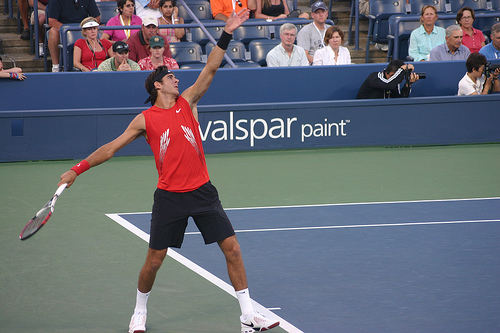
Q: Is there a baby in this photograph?
A: No, there are no babies.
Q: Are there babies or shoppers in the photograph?
A: No, there are no babies or shoppers.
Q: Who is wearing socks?
A: The man is wearing socks.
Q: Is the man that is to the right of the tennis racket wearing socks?
A: Yes, the man is wearing socks.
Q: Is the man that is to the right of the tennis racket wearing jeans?
A: No, the man is wearing socks.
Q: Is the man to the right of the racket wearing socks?
A: Yes, the man is wearing socks.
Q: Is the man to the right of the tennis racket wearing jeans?
A: No, the man is wearing socks.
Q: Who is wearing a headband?
A: The man is wearing a headband.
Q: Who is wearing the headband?
A: The man is wearing a headband.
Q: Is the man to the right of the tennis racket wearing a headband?
A: Yes, the man is wearing a headband.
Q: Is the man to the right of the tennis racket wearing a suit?
A: No, the man is wearing a headband.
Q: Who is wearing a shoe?
A: The man is wearing a shoe.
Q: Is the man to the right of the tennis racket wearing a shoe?
A: Yes, the man is wearing a shoe.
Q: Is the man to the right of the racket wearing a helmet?
A: No, the man is wearing a shoe.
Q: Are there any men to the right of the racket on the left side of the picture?
A: Yes, there is a man to the right of the tennis racket.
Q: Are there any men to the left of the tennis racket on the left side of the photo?
A: No, the man is to the right of the tennis racket.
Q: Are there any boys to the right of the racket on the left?
A: No, there is a man to the right of the tennis racket.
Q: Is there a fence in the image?
A: No, there are no fences.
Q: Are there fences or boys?
A: No, there are no fences or boys.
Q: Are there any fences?
A: No, there are no fences.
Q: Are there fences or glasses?
A: No, there are no fences or glasses.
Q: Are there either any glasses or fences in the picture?
A: No, there are no fences or glasses.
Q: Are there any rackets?
A: Yes, there is a racket.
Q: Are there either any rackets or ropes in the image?
A: Yes, there is a racket.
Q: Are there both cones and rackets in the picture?
A: No, there is a racket but no cones.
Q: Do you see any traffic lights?
A: No, there are no traffic lights.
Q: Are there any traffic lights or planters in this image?
A: No, there are no traffic lights or planters.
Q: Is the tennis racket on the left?
A: Yes, the tennis racket is on the left of the image.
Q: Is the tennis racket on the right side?
A: No, the tennis racket is on the left of the image.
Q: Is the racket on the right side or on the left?
A: The racket is on the left of the image.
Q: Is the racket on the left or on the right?
A: The racket is on the left of the image.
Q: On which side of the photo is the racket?
A: The racket is on the left of the image.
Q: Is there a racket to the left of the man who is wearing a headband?
A: Yes, there is a racket to the left of the man.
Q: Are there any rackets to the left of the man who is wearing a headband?
A: Yes, there is a racket to the left of the man.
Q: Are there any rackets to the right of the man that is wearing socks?
A: No, the racket is to the left of the man.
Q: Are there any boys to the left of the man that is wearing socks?
A: No, there is a racket to the left of the man.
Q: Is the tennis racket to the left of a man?
A: Yes, the tennis racket is to the left of a man.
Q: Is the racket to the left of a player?
A: No, the racket is to the left of a man.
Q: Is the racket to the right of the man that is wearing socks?
A: No, the racket is to the left of the man.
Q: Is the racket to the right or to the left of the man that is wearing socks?
A: The racket is to the left of the man.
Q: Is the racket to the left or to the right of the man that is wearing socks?
A: The racket is to the left of the man.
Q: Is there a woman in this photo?
A: Yes, there is a woman.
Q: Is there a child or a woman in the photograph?
A: Yes, there is a woman.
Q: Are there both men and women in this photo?
A: Yes, there are both a woman and a man.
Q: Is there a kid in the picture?
A: No, there are no children.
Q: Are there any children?
A: No, there are no children.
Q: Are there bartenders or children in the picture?
A: No, there are no children or bartenders.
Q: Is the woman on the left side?
A: Yes, the woman is on the left of the image.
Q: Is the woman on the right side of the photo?
A: No, the woman is on the left of the image.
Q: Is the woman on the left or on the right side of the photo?
A: The woman is on the left of the image.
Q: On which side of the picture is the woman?
A: The woman is on the left of the image.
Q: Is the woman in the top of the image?
A: Yes, the woman is in the top of the image.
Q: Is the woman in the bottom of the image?
A: No, the woman is in the top of the image.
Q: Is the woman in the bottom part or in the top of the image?
A: The woman is in the top of the image.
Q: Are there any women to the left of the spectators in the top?
A: Yes, there is a woman to the left of the spectators.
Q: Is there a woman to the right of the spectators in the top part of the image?
A: No, the woman is to the left of the spectators.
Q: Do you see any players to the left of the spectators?
A: No, there is a woman to the left of the spectators.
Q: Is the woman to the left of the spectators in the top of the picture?
A: Yes, the woman is to the left of the spectators.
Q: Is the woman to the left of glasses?
A: No, the woman is to the left of the spectators.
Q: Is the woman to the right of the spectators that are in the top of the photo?
A: No, the woman is to the left of the spectators.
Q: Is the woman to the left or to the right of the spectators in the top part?
A: The woman is to the left of the spectators.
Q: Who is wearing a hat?
A: The woman is wearing a hat.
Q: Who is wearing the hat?
A: The woman is wearing a hat.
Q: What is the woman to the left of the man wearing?
A: The woman is wearing a hat.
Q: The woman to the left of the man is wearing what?
A: The woman is wearing a hat.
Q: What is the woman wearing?
A: The woman is wearing a hat.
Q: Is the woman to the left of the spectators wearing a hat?
A: Yes, the woman is wearing a hat.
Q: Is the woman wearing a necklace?
A: No, the woman is wearing a hat.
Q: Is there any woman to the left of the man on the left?
A: Yes, there is a woman to the left of the man.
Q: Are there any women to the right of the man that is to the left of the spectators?
A: No, the woman is to the left of the man.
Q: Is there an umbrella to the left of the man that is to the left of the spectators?
A: No, there is a woman to the left of the man.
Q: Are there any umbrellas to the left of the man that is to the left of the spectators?
A: No, there is a woman to the left of the man.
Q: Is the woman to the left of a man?
A: Yes, the woman is to the left of a man.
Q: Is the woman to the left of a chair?
A: No, the woman is to the left of a man.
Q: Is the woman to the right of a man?
A: No, the woman is to the left of a man.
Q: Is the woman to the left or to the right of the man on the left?
A: The woman is to the left of the man.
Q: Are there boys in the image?
A: No, there are no boys.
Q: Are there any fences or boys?
A: No, there are no boys or fences.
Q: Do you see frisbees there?
A: No, there are no frisbees.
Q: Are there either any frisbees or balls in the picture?
A: No, there are no frisbees or balls.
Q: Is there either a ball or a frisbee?
A: No, there are no frisbees or balls.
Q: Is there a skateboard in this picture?
A: No, there are no skateboards.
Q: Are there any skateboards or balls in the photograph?
A: No, there are no skateboards or balls.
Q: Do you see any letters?
A: Yes, there are letters.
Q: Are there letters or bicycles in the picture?
A: Yes, there are letters.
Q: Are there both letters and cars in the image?
A: No, there are letters but no cars.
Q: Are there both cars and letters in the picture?
A: No, there are letters but no cars.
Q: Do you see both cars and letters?
A: No, there are letters but no cars.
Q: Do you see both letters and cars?
A: No, there are letters but no cars.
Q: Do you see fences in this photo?
A: No, there are no fences.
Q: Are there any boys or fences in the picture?
A: No, there are no fences or boys.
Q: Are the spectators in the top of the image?
A: Yes, the spectators are in the top of the image.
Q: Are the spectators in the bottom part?
A: No, the spectators are in the top of the image.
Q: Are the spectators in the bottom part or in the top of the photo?
A: The spectators are in the top of the image.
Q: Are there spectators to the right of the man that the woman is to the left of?
A: Yes, there are spectators to the right of the man.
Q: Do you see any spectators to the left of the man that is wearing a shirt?
A: No, the spectators are to the right of the man.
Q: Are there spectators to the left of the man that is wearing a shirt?
A: No, the spectators are to the right of the man.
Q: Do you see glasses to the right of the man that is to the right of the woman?
A: No, there are spectators to the right of the man.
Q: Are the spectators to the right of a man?
A: Yes, the spectators are to the right of a man.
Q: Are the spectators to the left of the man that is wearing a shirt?
A: No, the spectators are to the right of the man.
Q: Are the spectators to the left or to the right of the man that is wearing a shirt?
A: The spectators are to the right of the man.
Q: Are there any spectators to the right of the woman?
A: Yes, there are spectators to the right of the woman.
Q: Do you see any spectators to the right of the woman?
A: Yes, there are spectators to the right of the woman.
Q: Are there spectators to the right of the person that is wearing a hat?
A: Yes, there are spectators to the right of the woman.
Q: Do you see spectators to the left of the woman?
A: No, the spectators are to the right of the woman.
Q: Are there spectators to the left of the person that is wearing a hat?
A: No, the spectators are to the right of the woman.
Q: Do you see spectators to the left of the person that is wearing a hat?
A: No, the spectators are to the right of the woman.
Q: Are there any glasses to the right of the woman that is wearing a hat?
A: No, there are spectators to the right of the woman.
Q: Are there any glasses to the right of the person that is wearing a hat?
A: No, there are spectators to the right of the woman.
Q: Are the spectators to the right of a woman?
A: Yes, the spectators are to the right of a woman.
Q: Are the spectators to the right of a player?
A: No, the spectators are to the right of a woman.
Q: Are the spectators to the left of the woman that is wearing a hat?
A: No, the spectators are to the right of the woman.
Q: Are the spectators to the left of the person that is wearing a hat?
A: No, the spectators are to the right of the woman.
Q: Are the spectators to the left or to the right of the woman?
A: The spectators are to the right of the woman.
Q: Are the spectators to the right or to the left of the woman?
A: The spectators are to the right of the woman.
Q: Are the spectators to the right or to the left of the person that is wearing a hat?
A: The spectators are to the right of the woman.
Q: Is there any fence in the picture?
A: No, there are no fences.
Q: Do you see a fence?
A: No, there are no fences.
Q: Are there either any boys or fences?
A: No, there are no fences or boys.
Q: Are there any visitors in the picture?
A: No, there are no visitors.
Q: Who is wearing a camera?
A: The man is wearing a camera.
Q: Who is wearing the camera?
A: The man is wearing a camera.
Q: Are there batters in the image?
A: No, there are no batters.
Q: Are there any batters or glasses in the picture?
A: No, there are no batters or glasses.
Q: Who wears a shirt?
A: The man wears a shirt.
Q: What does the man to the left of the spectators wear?
A: The man wears a shirt.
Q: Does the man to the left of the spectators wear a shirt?
A: Yes, the man wears a shirt.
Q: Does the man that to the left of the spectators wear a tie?
A: No, the man wears a shirt.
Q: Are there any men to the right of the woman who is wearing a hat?
A: Yes, there is a man to the right of the woman.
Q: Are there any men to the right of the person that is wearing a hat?
A: Yes, there is a man to the right of the woman.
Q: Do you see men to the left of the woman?
A: No, the man is to the right of the woman.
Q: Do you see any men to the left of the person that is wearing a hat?
A: No, the man is to the right of the woman.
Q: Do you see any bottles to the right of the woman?
A: No, there is a man to the right of the woman.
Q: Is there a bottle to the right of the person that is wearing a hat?
A: No, there is a man to the right of the woman.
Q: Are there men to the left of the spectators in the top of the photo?
A: Yes, there is a man to the left of the spectators.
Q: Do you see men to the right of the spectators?
A: No, the man is to the left of the spectators.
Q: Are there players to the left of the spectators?
A: No, there is a man to the left of the spectators.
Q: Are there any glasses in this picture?
A: No, there are no glasses.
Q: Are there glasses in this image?
A: No, there are no glasses.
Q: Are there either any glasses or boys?
A: No, there are no glasses or boys.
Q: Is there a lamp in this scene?
A: No, there are no lamps.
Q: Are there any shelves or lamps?
A: No, there are no lamps or shelves.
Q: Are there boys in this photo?
A: No, there are no boys.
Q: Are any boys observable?
A: No, there are no boys.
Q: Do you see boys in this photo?
A: No, there are no boys.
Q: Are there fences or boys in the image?
A: No, there are no boys or fences.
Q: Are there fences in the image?
A: No, there are no fences.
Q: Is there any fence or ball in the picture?
A: No, there are no fences or balls.